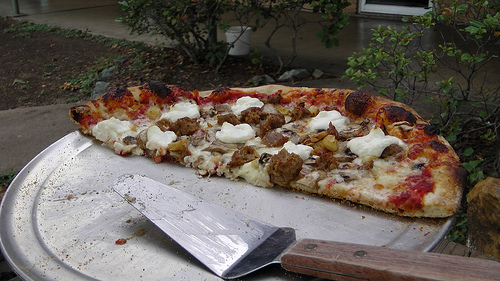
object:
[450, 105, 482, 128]
ground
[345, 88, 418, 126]
edge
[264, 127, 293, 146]
meattopping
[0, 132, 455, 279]
silver pan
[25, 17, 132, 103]
weed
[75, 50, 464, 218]
pizza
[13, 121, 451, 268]
pizza tray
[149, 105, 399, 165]
white cheese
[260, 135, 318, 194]
sausage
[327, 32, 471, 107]
background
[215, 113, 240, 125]
meat topping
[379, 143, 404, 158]
meat topping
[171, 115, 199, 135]
meat topping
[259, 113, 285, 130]
meat topping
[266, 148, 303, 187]
meat topping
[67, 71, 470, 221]
crust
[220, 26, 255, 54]
bucket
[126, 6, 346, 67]
bush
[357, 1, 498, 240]
plant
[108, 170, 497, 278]
spatula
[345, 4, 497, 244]
bush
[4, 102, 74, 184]
sidewalk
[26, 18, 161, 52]
edge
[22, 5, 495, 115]
sidewalk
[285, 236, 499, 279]
handle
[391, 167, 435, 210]
sauce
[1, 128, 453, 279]
tray